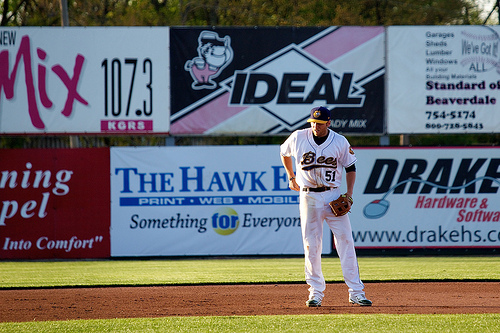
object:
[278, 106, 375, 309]
player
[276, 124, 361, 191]
jersey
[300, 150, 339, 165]
bees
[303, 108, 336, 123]
cap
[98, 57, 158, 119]
numbers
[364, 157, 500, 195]
drake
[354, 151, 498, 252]
banner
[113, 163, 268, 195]
hawk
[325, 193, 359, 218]
glove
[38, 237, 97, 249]
comfort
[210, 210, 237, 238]
circle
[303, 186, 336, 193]
belt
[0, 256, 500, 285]
grass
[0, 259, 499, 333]
field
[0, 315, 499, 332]
grass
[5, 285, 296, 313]
dirt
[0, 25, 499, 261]
advertising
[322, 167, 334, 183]
51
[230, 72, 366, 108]
ideal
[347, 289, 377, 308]
shoes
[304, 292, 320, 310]
shoes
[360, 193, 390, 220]
mouse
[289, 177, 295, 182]
watch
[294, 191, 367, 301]
pants